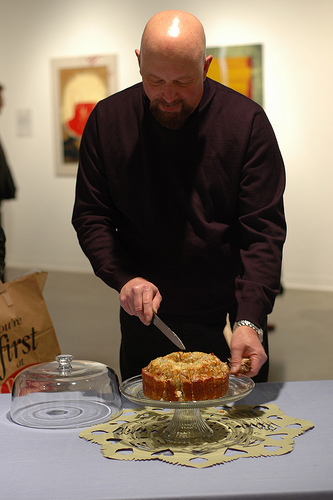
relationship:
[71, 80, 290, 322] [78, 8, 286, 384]
shirt of man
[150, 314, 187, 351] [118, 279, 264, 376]
knife in hands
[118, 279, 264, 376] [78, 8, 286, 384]
hands of man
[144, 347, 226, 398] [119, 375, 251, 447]
cake on dish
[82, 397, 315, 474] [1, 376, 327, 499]
place mat on table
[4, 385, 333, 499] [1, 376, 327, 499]
tablecloth on table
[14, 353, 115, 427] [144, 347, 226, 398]
glass to cover cake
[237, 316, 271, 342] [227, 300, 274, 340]
watch on wrist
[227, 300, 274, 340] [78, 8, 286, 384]
wrist of man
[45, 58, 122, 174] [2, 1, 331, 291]
painting on wall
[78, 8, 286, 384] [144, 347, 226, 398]
man cutting a cake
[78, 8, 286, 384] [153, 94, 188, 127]
man has a beard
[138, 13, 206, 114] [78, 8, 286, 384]
head of man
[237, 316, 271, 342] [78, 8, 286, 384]
watch of man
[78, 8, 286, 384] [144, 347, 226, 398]
man cutting cake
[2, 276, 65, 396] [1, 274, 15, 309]
shopping bag has handles